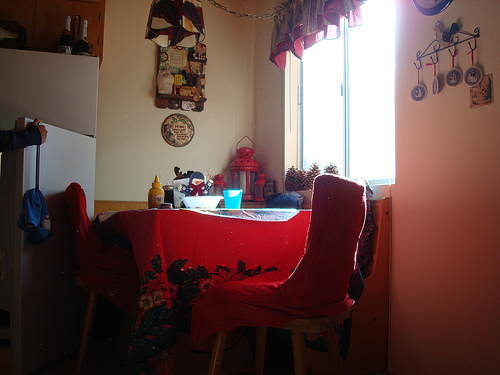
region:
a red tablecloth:
[82, 201, 355, 354]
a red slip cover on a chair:
[197, 178, 367, 362]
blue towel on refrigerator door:
[12, 180, 53, 243]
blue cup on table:
[222, 185, 244, 206]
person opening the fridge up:
[2, 113, 47, 158]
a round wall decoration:
[159, 112, 197, 147]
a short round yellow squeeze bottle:
[148, 175, 165, 206]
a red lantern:
[227, 135, 261, 202]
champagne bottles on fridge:
[54, 13, 92, 56]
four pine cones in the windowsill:
[285, 164, 339, 190]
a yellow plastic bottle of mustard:
[135, 165, 173, 213]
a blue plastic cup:
[220, 177, 249, 218]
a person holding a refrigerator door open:
[5, 105, 67, 167]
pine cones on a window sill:
[277, 159, 339, 199]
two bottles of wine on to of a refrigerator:
[58, 13, 90, 60]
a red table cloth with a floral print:
[110, 205, 308, 318]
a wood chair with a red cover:
[199, 154, 369, 359]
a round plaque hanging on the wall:
[158, 113, 200, 148]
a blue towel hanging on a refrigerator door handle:
[20, 169, 56, 271]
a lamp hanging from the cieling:
[141, 3, 293, 56]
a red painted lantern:
[231, 135, 261, 203]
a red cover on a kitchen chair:
[188, 174, 365, 336]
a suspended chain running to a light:
[142, 4, 283, 54]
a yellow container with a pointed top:
[146, 174, 163, 210]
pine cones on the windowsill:
[288, 165, 358, 193]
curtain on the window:
[266, 1, 372, 48]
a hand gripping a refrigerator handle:
[5, 112, 64, 162]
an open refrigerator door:
[2, 108, 115, 309]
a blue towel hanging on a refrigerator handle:
[15, 180, 57, 255]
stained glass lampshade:
[142, 7, 209, 45]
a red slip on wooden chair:
[196, 174, 361, 339]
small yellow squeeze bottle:
[149, 176, 165, 206]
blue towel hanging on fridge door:
[22, 188, 51, 240]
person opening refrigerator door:
[3, 115, 51, 156]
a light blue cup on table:
[222, 188, 243, 208]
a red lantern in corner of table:
[230, 134, 257, 201]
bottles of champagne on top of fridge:
[60, 13, 93, 57]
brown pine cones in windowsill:
[285, 163, 338, 190]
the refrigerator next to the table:
[0, 50, 98, 374]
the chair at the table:
[190, 174, 367, 374]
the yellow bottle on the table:
[146, 172, 164, 207]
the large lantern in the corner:
[229, 135, 259, 200]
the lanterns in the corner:
[211, 134, 266, 201]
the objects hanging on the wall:
[411, 19, 493, 109]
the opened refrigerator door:
[13, 114, 94, 372]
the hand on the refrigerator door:
[25, 114, 48, 144]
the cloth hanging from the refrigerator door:
[17, 186, 52, 248]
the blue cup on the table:
[222, 188, 242, 209]